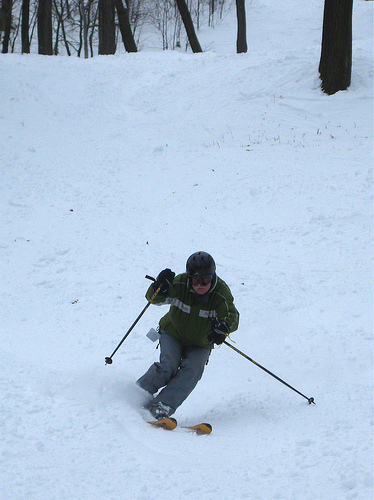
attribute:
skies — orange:
[125, 379, 215, 436]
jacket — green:
[142, 270, 244, 356]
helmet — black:
[182, 251, 213, 304]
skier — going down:
[134, 247, 241, 419]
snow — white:
[4, 390, 358, 498]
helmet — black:
[184, 250, 217, 274]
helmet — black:
[183, 251, 222, 285]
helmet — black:
[181, 252, 210, 279]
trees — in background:
[7, 4, 263, 55]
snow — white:
[28, 386, 150, 497]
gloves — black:
[151, 267, 231, 350]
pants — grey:
[146, 329, 193, 430]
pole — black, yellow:
[207, 325, 320, 405]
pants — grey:
[132, 328, 213, 419]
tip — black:
[203, 420, 213, 430]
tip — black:
[169, 418, 177, 423]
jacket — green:
[140, 261, 275, 358]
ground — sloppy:
[2, 4, 371, 498]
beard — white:
[182, 277, 220, 307]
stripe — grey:
[161, 295, 218, 322]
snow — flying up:
[94, 358, 166, 421]